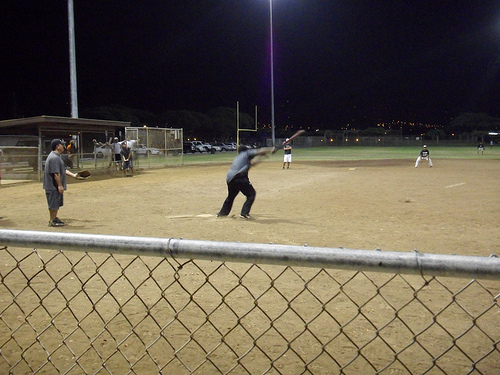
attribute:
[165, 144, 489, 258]
field — baseball